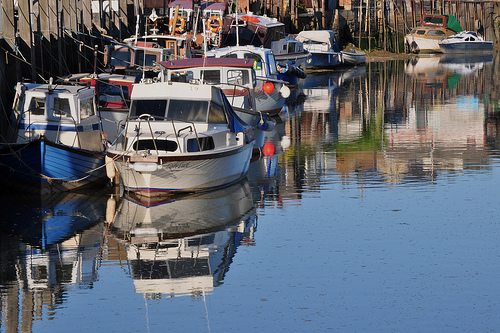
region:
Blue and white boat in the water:
[434, 24, 491, 66]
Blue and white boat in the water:
[403, 11, 447, 71]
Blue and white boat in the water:
[8, 67, 108, 210]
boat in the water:
[119, 76, 279, 210]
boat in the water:
[193, 36, 313, 134]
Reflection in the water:
[11, 207, 108, 290]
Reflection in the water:
[88, 169, 264, 286]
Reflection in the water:
[403, 49, 484, 97]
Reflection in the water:
[280, 41, 484, 156]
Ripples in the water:
[246, 266, 383, 330]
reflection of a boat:
[80, 183, 273, 310]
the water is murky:
[350, 200, 448, 310]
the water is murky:
[318, 225, 471, 328]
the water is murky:
[309, 263, 401, 318]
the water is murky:
[270, 255, 407, 306]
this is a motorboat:
[110, 75, 235, 178]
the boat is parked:
[106, 65, 252, 195]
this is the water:
[315, 223, 423, 328]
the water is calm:
[335, 210, 447, 322]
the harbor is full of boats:
[21, 14, 295, 180]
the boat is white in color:
[167, 83, 197, 97]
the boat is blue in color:
[38, 148, 70, 170]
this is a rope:
[43, 166, 70, 186]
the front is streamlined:
[121, 144, 161, 172]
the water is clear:
[330, 118, 462, 252]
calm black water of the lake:
[325, 109, 448, 210]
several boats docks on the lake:
[5, 0, 337, 198]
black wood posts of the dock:
[0, 8, 130, 71]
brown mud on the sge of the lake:
[371, 51, 398, 59]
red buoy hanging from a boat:
[258, 78, 278, 99]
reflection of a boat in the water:
[110, 175, 263, 296]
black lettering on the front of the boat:
[163, 160, 195, 174]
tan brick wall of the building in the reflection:
[441, 113, 483, 135]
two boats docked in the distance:
[398, 8, 493, 58]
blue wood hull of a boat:
[46, 152, 93, 189]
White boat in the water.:
[101, 78, 288, 202]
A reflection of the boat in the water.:
[96, 192, 271, 302]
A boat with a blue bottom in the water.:
[6, 78, 111, 193]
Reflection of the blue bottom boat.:
[7, 191, 111, 297]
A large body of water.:
[21, 57, 494, 323]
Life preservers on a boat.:
[164, 15, 224, 32]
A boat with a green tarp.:
[400, 9, 470, 62]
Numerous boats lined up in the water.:
[1, 0, 497, 197]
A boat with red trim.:
[60, 68, 140, 112]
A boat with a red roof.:
[154, 55, 268, 112]